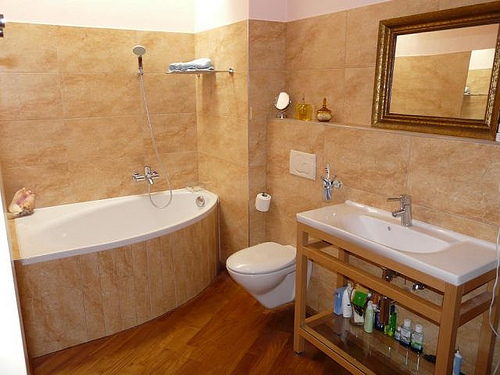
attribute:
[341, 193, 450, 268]
sink — silver, white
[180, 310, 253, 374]
floor — wooden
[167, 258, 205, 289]
tile — tan